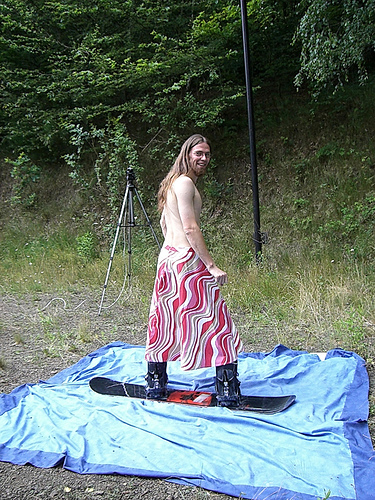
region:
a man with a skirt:
[66, 97, 299, 475]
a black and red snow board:
[79, 356, 307, 419]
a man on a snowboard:
[74, 93, 282, 471]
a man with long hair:
[101, 97, 267, 447]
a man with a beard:
[129, 101, 242, 487]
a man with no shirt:
[92, 72, 266, 457]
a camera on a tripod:
[81, 137, 165, 328]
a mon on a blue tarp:
[60, 94, 274, 497]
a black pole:
[228, 6, 278, 269]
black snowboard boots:
[128, 346, 247, 403]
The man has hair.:
[148, 115, 234, 285]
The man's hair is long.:
[151, 127, 239, 279]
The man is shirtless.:
[146, 113, 245, 294]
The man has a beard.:
[154, 121, 219, 211]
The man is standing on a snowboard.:
[89, 127, 300, 423]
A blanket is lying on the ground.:
[0, 279, 374, 499]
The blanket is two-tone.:
[0, 320, 373, 498]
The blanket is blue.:
[2, 313, 374, 498]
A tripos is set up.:
[36, 146, 187, 337]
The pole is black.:
[228, 0, 273, 271]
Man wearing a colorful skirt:
[144, 130, 244, 371]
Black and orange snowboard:
[89, 374, 296, 416]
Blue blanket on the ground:
[1, 341, 372, 498]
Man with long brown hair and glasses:
[156, 133, 212, 209]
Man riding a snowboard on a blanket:
[88, 132, 297, 415]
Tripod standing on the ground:
[95, 162, 159, 317]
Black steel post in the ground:
[238, 0, 264, 264]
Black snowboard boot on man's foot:
[215, 358, 242, 412]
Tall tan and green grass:
[244, 234, 374, 334]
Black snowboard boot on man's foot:
[143, 360, 168, 404]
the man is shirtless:
[144, 129, 247, 408]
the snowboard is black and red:
[86, 373, 298, 417]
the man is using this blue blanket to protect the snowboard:
[1, 335, 373, 498]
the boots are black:
[141, 356, 245, 410]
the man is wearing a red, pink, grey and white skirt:
[143, 242, 249, 371]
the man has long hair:
[155, 131, 214, 210]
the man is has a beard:
[186, 157, 209, 176]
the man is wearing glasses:
[187, 150, 213, 159]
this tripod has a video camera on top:
[95, 162, 166, 322]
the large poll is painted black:
[232, 0, 272, 275]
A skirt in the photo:
[150, 244, 238, 369]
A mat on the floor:
[165, 419, 300, 472]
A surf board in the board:
[87, 361, 288, 419]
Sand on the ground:
[30, 472, 113, 498]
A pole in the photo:
[245, 137, 274, 244]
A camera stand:
[95, 167, 164, 318]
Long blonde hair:
[152, 133, 190, 208]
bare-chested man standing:
[136, 127, 240, 392]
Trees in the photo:
[59, 20, 175, 108]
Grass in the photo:
[254, 271, 339, 318]